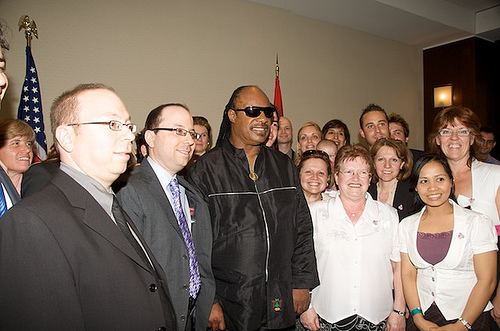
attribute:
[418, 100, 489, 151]
woman — tall red-haired 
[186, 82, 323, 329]
person — group, smiling 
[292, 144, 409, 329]
woman — short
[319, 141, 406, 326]
woman — wearing a shirt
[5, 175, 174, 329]
suit — grey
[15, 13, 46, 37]
eagle — on the flag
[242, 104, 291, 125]
glasses — on the face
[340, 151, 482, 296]
people — standing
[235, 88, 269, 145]
face — man's 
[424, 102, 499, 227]
woman — taller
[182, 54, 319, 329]
stevie wonder — standing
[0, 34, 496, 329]
people — standing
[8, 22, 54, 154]
flag — american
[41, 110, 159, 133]
man's face — man's 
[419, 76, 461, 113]
light — on the wall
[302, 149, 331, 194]
head —  woman's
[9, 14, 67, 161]
flag — American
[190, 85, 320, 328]
man — black  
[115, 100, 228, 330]
man — white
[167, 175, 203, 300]
tie — blue, white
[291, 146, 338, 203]
woman — shorter, white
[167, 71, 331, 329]
man — black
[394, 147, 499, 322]
woman — wearing a shirt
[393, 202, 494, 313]
outfit — white 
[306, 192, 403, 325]
blouse — white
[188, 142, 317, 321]
shirt — black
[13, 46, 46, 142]
flag — american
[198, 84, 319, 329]
black man — black 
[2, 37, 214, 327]
white people — white 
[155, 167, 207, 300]
purple tie — on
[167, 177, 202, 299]
neck tie —  purple, for neck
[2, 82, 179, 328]
guy — wearing a shirt, standing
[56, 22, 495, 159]
wall — background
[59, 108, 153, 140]
glasses — regular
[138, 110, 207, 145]
glasses — regular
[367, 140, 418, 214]
woman — wearing suit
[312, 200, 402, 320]
shirt — white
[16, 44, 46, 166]
flag — American flag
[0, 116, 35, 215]
woman — smiling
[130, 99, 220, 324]
man — wearing a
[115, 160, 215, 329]
suit — gray 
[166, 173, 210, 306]
tie — purple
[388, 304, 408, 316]
wrist — each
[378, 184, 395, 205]
shirt — tan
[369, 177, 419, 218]
blazer — black 